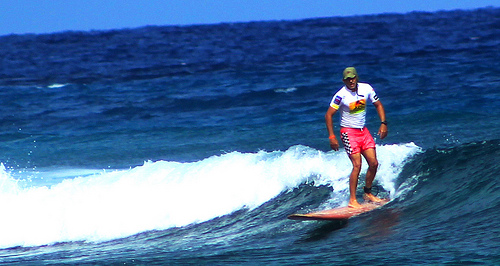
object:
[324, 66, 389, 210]
man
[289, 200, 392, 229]
surboard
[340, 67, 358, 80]
cap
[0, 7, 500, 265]
water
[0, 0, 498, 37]
sky